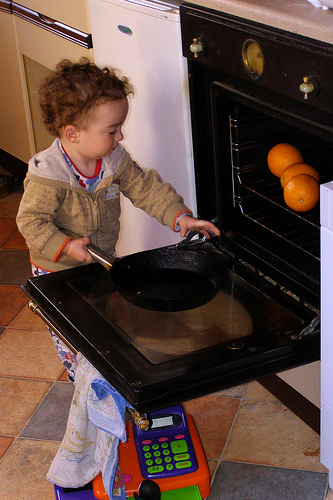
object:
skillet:
[59, 227, 223, 312]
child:
[15, 57, 221, 383]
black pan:
[110, 248, 224, 311]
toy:
[93, 402, 212, 500]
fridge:
[91, 1, 199, 255]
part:
[162, 62, 175, 92]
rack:
[236, 198, 321, 263]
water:
[46, 364, 153, 492]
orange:
[284, 173, 321, 213]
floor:
[1, 164, 327, 497]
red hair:
[38, 56, 133, 134]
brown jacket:
[15, 137, 192, 272]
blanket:
[45, 351, 134, 499]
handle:
[25, 299, 150, 429]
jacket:
[12, 134, 192, 274]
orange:
[280, 162, 319, 189]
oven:
[175, 3, 333, 329]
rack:
[240, 178, 324, 230]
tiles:
[4, 439, 57, 499]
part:
[253, 404, 283, 443]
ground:
[0, 435, 39, 498]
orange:
[267, 142, 303, 178]